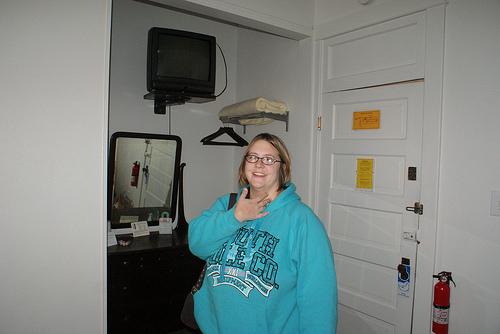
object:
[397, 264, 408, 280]
hanger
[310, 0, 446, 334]
door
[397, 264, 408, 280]
handle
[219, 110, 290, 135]
metal shelf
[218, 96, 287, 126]
blanket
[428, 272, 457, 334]
extinguisher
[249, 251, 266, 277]
letter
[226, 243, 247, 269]
letter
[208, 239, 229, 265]
letter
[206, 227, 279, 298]
design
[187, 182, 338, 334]
hoodie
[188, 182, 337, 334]
front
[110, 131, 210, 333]
dresser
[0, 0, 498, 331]
room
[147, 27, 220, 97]
tv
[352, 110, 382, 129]
yellow sign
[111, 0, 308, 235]
wall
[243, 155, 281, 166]
eyeglasses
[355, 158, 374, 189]
sign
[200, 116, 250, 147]
hanger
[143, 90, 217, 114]
shelf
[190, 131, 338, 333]
girl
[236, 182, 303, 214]
hood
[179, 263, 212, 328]
purse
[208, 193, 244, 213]
shoulder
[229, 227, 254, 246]
letter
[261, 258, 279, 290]
letter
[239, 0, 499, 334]
wall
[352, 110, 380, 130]
paper